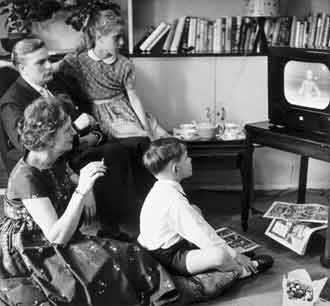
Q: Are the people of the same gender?
A: No, they are both male and female.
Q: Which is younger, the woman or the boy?
A: The boy is younger than the woman.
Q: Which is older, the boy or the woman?
A: The woman is older than the boy.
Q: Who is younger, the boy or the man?
A: The boy is younger than the man.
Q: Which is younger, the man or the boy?
A: The boy is younger than the man.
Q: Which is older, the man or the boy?
A: The man is older than the boy.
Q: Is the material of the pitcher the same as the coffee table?
A: No, the pitcher is made of glass and the coffee table is made of wood.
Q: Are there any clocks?
A: No, there are no clocks.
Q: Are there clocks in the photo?
A: No, there are no clocks.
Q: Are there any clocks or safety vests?
A: No, there are no clocks or safety vests.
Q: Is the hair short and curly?
A: Yes, the hair is short and curly.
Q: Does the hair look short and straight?
A: No, the hair is short but curly.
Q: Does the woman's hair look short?
A: Yes, the hair is short.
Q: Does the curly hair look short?
A: Yes, the hair is short.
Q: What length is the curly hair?
A: The hair is short.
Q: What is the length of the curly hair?
A: The hair is short.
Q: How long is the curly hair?
A: The hair is short.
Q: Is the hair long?
A: No, the hair is short.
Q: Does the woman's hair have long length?
A: No, the hair is short.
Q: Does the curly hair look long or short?
A: The hair is short.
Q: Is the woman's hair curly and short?
A: Yes, the hair is curly and short.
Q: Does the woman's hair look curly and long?
A: No, the hair is curly but short.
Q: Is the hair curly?
A: Yes, the hair is curly.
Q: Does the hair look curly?
A: Yes, the hair is curly.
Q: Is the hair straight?
A: No, the hair is curly.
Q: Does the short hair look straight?
A: No, the hair is curly.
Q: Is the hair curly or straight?
A: The hair is curly.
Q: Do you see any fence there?
A: No, there are no fences.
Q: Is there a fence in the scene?
A: No, there are no fences.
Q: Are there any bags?
A: No, there are no bags.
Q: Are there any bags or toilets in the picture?
A: No, there are no bags or toilets.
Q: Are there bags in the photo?
A: No, there are no bags.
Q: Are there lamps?
A: Yes, there is a lamp.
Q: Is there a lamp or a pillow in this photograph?
A: Yes, there is a lamp.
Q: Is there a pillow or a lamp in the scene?
A: Yes, there is a lamp.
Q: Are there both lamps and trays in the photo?
A: Yes, there are both a lamp and a tray.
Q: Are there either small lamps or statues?
A: Yes, there is a small lamp.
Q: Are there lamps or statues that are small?
A: Yes, the lamp is small.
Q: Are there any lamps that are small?
A: Yes, there is a small lamp.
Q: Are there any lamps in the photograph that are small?
A: Yes, there is a lamp that is small.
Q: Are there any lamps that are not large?
A: Yes, there is a small lamp.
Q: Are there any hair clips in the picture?
A: No, there are no hair clips.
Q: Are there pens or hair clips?
A: No, there are no hair clips or pens.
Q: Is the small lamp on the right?
A: Yes, the lamp is on the right of the image.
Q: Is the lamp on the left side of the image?
A: No, the lamp is on the right of the image.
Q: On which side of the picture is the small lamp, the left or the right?
A: The lamp is on the right of the image.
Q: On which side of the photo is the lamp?
A: The lamp is on the right of the image.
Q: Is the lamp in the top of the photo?
A: Yes, the lamp is in the top of the image.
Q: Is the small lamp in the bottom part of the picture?
A: No, the lamp is in the top of the image.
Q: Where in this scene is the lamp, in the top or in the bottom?
A: The lamp is in the top of the image.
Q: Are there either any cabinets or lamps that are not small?
A: No, there is a lamp but it is small.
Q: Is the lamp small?
A: Yes, the lamp is small.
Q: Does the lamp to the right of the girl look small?
A: Yes, the lamp is small.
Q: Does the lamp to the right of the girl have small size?
A: Yes, the lamp is small.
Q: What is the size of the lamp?
A: The lamp is small.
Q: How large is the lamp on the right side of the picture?
A: The lamp is small.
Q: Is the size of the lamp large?
A: No, the lamp is small.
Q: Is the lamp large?
A: No, the lamp is small.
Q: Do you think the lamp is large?
A: No, the lamp is small.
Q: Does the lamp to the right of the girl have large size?
A: No, the lamp is small.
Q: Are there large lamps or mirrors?
A: No, there is a lamp but it is small.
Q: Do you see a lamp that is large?
A: No, there is a lamp but it is small.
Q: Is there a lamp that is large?
A: No, there is a lamp but it is small.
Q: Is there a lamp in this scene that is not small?
A: No, there is a lamp but it is small.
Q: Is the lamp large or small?
A: The lamp is small.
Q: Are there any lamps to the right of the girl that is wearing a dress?
A: Yes, there is a lamp to the right of the girl.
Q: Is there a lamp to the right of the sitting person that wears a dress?
A: Yes, there is a lamp to the right of the girl.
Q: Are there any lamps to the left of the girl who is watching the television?
A: No, the lamp is to the right of the girl.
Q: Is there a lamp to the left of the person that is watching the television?
A: No, the lamp is to the right of the girl.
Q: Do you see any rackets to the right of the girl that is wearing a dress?
A: No, there is a lamp to the right of the girl.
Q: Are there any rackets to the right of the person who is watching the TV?
A: No, there is a lamp to the right of the girl.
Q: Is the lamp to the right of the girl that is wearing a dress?
A: Yes, the lamp is to the right of the girl.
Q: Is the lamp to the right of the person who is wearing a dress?
A: Yes, the lamp is to the right of the girl.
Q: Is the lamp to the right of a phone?
A: No, the lamp is to the right of the girl.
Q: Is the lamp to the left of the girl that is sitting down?
A: No, the lamp is to the right of the girl.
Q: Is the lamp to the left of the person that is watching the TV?
A: No, the lamp is to the right of the girl.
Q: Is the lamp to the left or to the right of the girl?
A: The lamp is to the right of the girl.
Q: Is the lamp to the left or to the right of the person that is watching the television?
A: The lamp is to the right of the girl.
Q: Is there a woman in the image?
A: Yes, there is a woman.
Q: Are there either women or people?
A: Yes, there is a woman.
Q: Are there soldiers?
A: No, there are no soldiers.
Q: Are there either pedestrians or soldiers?
A: No, there are no soldiers or pedestrians.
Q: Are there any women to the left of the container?
A: Yes, there is a woman to the left of the container.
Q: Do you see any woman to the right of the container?
A: No, the woman is to the left of the container.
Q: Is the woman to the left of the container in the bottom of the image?
A: Yes, the woman is to the left of the container.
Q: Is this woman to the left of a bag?
A: No, the woman is to the left of the container.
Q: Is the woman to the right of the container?
A: No, the woman is to the left of the container.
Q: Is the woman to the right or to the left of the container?
A: The woman is to the left of the container.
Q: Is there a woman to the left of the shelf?
A: Yes, there is a woman to the left of the shelf.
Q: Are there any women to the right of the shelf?
A: No, the woman is to the left of the shelf.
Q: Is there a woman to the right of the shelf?
A: No, the woman is to the left of the shelf.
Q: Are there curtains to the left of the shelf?
A: No, there is a woman to the left of the shelf.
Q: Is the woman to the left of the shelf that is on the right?
A: Yes, the woman is to the left of the shelf.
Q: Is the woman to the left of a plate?
A: No, the woman is to the left of the shelf.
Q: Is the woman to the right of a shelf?
A: No, the woman is to the left of a shelf.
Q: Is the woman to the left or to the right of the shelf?
A: The woman is to the left of the shelf.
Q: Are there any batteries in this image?
A: No, there are no batteries.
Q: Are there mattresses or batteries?
A: No, there are no batteries or mattresses.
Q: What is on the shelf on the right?
A: The newspaper is on the shelf.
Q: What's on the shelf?
A: The newspaper is on the shelf.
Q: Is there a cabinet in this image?
A: No, there are no cabinets.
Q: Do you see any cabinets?
A: No, there are no cabinets.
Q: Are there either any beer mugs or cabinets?
A: No, there are no cabinets or beer mugs.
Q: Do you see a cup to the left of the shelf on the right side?
A: Yes, there are cups to the left of the shelf.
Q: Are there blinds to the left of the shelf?
A: No, there are cups to the left of the shelf.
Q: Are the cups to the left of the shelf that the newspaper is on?
A: Yes, the cups are to the left of the shelf.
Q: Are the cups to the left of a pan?
A: No, the cups are to the left of the shelf.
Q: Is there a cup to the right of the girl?
A: Yes, there are cups to the right of the girl.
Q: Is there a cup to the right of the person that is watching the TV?
A: Yes, there are cups to the right of the girl.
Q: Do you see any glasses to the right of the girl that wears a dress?
A: No, there are cups to the right of the girl.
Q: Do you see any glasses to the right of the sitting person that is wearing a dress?
A: No, there are cups to the right of the girl.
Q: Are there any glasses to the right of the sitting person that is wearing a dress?
A: No, there are cups to the right of the girl.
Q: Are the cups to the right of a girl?
A: Yes, the cups are to the right of a girl.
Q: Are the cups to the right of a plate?
A: No, the cups are to the right of a girl.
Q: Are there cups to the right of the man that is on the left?
A: Yes, there are cups to the right of the man.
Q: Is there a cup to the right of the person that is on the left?
A: Yes, there are cups to the right of the man.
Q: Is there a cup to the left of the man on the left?
A: No, the cups are to the right of the man.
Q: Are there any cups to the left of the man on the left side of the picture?
A: No, the cups are to the right of the man.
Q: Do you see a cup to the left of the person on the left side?
A: No, the cups are to the right of the man.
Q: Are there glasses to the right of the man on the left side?
A: No, there are cups to the right of the man.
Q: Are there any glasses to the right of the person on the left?
A: No, there are cups to the right of the man.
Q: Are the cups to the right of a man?
A: Yes, the cups are to the right of a man.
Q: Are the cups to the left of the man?
A: No, the cups are to the right of the man.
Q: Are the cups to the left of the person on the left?
A: No, the cups are to the right of the man.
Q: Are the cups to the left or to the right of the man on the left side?
A: The cups are to the right of the man.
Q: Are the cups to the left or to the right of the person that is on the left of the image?
A: The cups are to the right of the man.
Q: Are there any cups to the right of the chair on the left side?
A: Yes, there are cups to the right of the chair.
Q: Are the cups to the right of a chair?
A: Yes, the cups are to the right of a chair.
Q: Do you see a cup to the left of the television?
A: Yes, there are cups to the left of the television.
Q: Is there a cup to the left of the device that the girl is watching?
A: Yes, there are cups to the left of the television.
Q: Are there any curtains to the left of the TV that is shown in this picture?
A: No, there are cups to the left of the TV.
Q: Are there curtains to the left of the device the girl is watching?
A: No, there are cups to the left of the TV.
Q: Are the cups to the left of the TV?
A: Yes, the cups are to the left of the TV.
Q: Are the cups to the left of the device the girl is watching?
A: Yes, the cups are to the left of the TV.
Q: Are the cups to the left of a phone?
A: No, the cups are to the left of the TV.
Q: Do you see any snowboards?
A: No, there are no snowboards.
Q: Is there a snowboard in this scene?
A: No, there are no snowboards.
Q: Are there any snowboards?
A: No, there are no snowboards.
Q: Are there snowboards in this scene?
A: No, there are no snowboards.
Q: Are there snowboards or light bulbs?
A: No, there are no snowboards or light bulbs.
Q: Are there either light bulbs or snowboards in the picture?
A: No, there are no snowboards or light bulbs.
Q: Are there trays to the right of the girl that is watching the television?
A: Yes, there is a tray to the right of the girl.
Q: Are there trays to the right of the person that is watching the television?
A: Yes, there is a tray to the right of the girl.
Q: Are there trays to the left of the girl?
A: No, the tray is to the right of the girl.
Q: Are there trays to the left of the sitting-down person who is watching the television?
A: No, the tray is to the right of the girl.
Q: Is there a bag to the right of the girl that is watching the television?
A: No, there is a tray to the right of the girl.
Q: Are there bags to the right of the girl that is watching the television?
A: No, there is a tray to the right of the girl.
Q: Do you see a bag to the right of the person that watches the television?
A: No, there is a tray to the right of the girl.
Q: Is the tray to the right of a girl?
A: Yes, the tray is to the right of a girl.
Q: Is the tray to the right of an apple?
A: No, the tray is to the right of a girl.